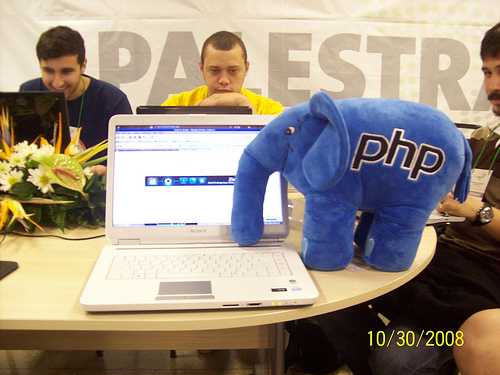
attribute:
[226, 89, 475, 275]
stuffed animal — blue, elephant, plush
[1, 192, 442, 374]
table — light brown, wooden, tan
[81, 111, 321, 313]
laptop — white, on, open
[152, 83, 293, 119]
shirt — yellow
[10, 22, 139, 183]
man — smiling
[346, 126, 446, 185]
letters — black, white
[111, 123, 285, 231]
screen — on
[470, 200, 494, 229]
watch — flexible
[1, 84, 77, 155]
laptop — black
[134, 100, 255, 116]
laptop — black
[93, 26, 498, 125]
letters — grey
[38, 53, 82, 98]
face — smiling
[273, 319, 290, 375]
post — metal